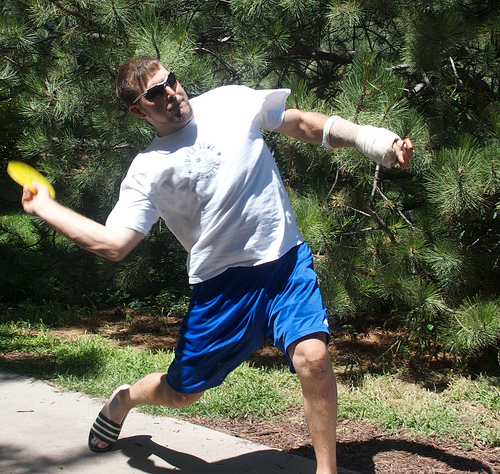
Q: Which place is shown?
A: It is a park.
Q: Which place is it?
A: It is a park.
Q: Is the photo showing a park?
A: Yes, it is showing a park.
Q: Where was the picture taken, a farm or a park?
A: It was taken at a park.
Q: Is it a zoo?
A: No, it is a park.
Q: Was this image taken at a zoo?
A: No, the picture was taken in a park.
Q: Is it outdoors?
A: Yes, it is outdoors.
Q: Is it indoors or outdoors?
A: It is outdoors.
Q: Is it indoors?
A: No, it is outdoors.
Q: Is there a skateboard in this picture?
A: No, there are no skateboards.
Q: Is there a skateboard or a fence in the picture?
A: No, there are no skateboards or fences.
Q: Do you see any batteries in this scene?
A: No, there are no batteries.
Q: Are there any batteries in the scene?
A: No, there are no batteries.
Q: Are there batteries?
A: No, there are no batteries.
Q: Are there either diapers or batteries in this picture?
A: No, there are no batteries or diapers.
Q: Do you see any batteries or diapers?
A: No, there are no batteries or diapers.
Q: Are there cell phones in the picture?
A: No, there are no cell phones.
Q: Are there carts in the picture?
A: No, there are no carts.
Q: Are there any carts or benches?
A: No, there are no carts or benches.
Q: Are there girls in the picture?
A: No, there are no girls.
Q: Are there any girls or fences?
A: No, there are no girls or fences.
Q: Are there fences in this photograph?
A: No, there are no fences.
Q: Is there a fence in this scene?
A: No, there are no fences.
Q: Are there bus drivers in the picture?
A: No, there are no bus drivers.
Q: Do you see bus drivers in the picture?
A: No, there are no bus drivers.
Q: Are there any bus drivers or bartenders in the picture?
A: No, there are no bus drivers or bartenders.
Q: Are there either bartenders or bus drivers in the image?
A: No, there are no bus drivers or bartenders.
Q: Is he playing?
A: Yes, the man is playing.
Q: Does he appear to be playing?
A: Yes, the man is playing.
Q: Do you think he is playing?
A: Yes, the man is playing.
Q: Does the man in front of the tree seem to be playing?
A: Yes, the man is playing.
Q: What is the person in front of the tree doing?
A: The man is playing.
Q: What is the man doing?
A: The man is playing.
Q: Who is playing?
A: The man is playing.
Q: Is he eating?
A: No, the man is playing.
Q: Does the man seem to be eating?
A: No, the man is playing.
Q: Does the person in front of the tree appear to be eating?
A: No, the man is playing.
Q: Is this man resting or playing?
A: The man is playing.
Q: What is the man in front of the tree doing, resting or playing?
A: The man is playing.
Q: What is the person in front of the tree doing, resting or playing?
A: The man is playing.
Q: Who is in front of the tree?
A: The man is in front of the tree.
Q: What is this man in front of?
A: The man is in front of the tree.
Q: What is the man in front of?
A: The man is in front of the tree.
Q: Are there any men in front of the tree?
A: Yes, there is a man in front of the tree.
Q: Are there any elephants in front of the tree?
A: No, there is a man in front of the tree.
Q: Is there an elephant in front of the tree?
A: No, there is a man in front of the tree.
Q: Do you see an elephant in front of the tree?
A: No, there is a man in front of the tree.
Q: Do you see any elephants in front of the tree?
A: No, there is a man in front of the tree.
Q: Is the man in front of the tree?
A: Yes, the man is in front of the tree.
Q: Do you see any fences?
A: No, there are no fences.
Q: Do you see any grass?
A: Yes, there is grass.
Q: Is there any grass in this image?
A: Yes, there is grass.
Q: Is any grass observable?
A: Yes, there is grass.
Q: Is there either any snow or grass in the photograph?
A: Yes, there is grass.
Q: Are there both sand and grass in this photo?
A: No, there is grass but no sand.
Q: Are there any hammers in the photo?
A: No, there are no hammers.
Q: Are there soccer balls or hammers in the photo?
A: No, there are no hammers or soccer balls.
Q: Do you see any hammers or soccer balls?
A: No, there are no hammers or soccer balls.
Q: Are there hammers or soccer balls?
A: No, there are no hammers or soccer balls.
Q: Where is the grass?
A: The grass is on the ground.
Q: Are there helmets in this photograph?
A: No, there are no helmets.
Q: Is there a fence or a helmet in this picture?
A: No, there are no helmets or fences.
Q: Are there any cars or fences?
A: No, there are no fences or cars.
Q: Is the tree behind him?
A: Yes, the tree is behind the man.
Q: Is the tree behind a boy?
A: No, the tree is behind the man.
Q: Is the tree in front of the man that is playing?
A: No, the tree is behind the man.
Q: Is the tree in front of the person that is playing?
A: No, the tree is behind the man.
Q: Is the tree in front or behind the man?
A: The tree is behind the man.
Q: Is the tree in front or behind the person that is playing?
A: The tree is behind the man.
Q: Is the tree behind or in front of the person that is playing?
A: The tree is behind the man.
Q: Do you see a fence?
A: No, there are no fences.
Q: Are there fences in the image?
A: No, there are no fences.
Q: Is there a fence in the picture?
A: No, there are no fences.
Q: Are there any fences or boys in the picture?
A: No, there are no fences or boys.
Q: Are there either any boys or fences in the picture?
A: No, there are no fences or boys.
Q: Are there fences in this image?
A: No, there are no fences.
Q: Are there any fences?
A: No, there are no fences.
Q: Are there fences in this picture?
A: No, there are no fences.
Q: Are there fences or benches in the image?
A: No, there are no fences or benches.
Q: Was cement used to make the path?
A: Yes, the path is made of cement.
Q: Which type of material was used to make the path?
A: The path is made of cement.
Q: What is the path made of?
A: The path is made of concrete.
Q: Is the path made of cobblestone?
A: No, the path is made of cement.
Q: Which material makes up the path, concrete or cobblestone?
A: The path is made of concrete.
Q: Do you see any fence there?
A: No, there are no fences.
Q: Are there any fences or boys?
A: No, there are no fences or boys.